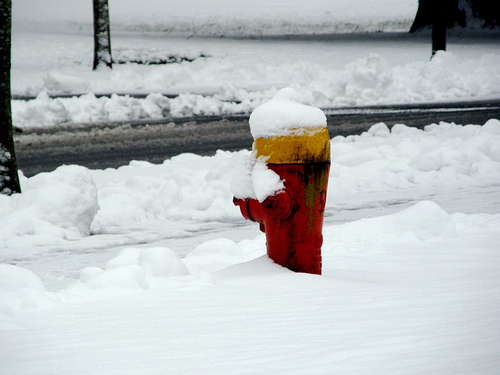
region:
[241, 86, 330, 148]
Snow atop a fire hydrant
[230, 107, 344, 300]
A red fire hydrant with a yellow top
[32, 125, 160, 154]
Slushy snow in a road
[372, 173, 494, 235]
A scraped snowy sidewalk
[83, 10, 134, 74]
A snow covered tree trunk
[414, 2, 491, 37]
The edge of a building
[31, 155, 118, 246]
A large snowball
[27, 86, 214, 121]
Snow piled up next to the road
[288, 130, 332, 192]
Dark stains on a fire hydrant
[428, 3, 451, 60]
A tree trunk not covered in snow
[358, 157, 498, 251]
a path in the snow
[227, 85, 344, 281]
red and yellow fire hydrant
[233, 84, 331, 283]
snow on the fire hydrant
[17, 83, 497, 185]
slushy snow on the road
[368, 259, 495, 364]
snow on ground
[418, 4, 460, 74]
tree trunk in the snow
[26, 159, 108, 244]
pile of snow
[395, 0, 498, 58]
large and small tree trunk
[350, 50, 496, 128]
snow piled up on side of road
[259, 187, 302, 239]
nozzle on fire hydrant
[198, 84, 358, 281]
a fire hydrant in the snow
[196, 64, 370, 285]
a fire hydrant covered in snow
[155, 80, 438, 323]
a yellow and red fire hydrant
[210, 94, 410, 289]
a fire hydrant in the cold weather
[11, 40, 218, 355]
snow on the street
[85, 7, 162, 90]
snow on the trees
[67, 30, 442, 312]
snow is covering everything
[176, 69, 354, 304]
the fire hydrant is surrounded by snow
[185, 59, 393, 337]
white snow is on the ground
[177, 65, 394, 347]
white snow is on the fire hydrant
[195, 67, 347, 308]
a fire hydrate on the street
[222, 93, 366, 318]
a red and yellow fire hydrate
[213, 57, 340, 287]
a fire hydrate covered in snow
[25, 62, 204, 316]
street covered in snow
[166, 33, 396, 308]
snow on the ground during the day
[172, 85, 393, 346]
snow surrounding the fire hydrate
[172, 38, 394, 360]
snow surrounding the red and yellow fire hydrant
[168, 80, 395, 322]
a red and yellow fire hydrant during the day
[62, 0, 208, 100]
a tree in the snow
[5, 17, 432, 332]
fire hydrant in the cold weather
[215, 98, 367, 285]
Red and yellow fire hydrant next to a sidewalk.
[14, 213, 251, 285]
slightly plowed sidewalk for people to walk on.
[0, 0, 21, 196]
Tree stem by the side of the road.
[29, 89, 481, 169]
Recently plowed road that has evidence of cars moving down it.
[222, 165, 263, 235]
Fire hydrant hose attachment side.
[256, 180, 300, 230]
Fire hydrant water control mechanism.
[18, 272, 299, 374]
Snow pack along the side of the road.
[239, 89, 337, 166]
Fire hydrant yellow to for identification.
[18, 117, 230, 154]
Slush in the middle of the road indicating that the snow is very wet.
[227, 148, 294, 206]
Snow pack on the fire hydrant indicating a recent storm.